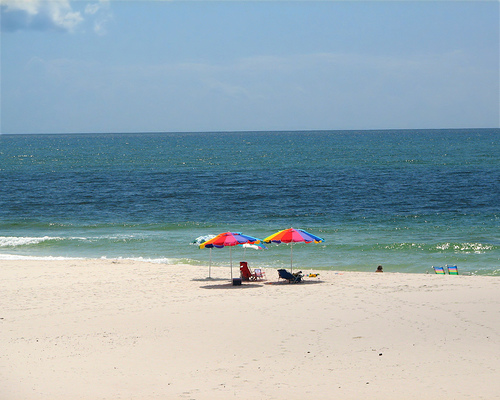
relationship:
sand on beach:
[4, 254, 498, 396] [4, 247, 497, 398]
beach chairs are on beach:
[432, 263, 462, 280] [4, 247, 497, 398]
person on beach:
[373, 262, 388, 277] [4, 247, 497, 398]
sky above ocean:
[3, 8, 497, 130] [3, 129, 496, 276]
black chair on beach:
[274, 265, 305, 286] [4, 247, 497, 398]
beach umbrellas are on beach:
[198, 220, 326, 256] [4, 247, 497, 398]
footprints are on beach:
[190, 283, 492, 397] [4, 247, 497, 398]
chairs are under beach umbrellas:
[229, 261, 316, 290] [198, 220, 326, 256]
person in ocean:
[373, 262, 388, 277] [3, 129, 496, 276]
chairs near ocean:
[229, 261, 316, 290] [3, 129, 496, 276]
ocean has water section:
[3, 129, 496, 276] [9, 157, 496, 227]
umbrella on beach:
[188, 233, 217, 245] [4, 247, 497, 398]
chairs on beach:
[229, 261, 316, 290] [4, 247, 497, 398]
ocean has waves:
[3, 129, 496, 276] [9, 212, 175, 247]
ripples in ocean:
[380, 241, 491, 254] [3, 129, 496, 276]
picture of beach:
[5, 5, 496, 396] [4, 247, 497, 398]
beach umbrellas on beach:
[198, 220, 326, 256] [4, 247, 497, 398]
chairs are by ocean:
[229, 261, 316, 290] [3, 129, 496, 276]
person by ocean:
[373, 262, 388, 277] [3, 129, 496, 276]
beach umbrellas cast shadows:
[198, 220, 326, 256] [191, 275, 290, 293]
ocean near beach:
[3, 129, 496, 276] [4, 247, 497, 398]